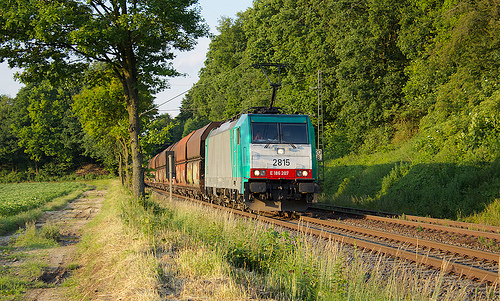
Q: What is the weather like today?
A: It is clear.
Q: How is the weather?
A: It is clear.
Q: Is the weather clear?
A: Yes, it is clear.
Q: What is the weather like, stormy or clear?
A: It is clear.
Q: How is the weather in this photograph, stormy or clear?
A: It is clear.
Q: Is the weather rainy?
A: No, it is clear.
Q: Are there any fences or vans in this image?
A: No, there are no fences or vans.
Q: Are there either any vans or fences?
A: No, there are no fences or vans.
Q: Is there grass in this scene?
A: Yes, there is grass.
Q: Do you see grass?
A: Yes, there is grass.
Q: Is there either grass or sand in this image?
A: Yes, there is grass.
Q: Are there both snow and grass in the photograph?
A: No, there is grass but no snow.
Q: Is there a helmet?
A: No, there are no helmets.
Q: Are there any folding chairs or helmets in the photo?
A: No, there are no helmets or folding chairs.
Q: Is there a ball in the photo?
A: No, there are no balls.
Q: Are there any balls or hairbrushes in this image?
A: No, there are no balls or hairbrushes.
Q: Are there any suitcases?
A: No, there are no suitcases.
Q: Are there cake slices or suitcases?
A: No, there are no suitcases or cake slices.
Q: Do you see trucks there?
A: No, there are no trucks.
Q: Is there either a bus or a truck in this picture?
A: No, there are no trucks or buses.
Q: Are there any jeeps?
A: No, there are no jeeps.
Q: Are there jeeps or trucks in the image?
A: No, there are no jeeps or trucks.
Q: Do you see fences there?
A: No, there are no fences.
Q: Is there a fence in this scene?
A: No, there are no fences.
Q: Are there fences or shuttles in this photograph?
A: No, there are no fences or shuttles.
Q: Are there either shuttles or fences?
A: No, there are no fences or shuttles.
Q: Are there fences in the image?
A: No, there are no fences.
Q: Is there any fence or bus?
A: No, there are no fences or buses.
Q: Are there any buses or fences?
A: No, there are no fences or buses.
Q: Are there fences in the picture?
A: No, there are no fences.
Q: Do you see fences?
A: No, there are no fences.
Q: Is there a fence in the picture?
A: No, there are no fences.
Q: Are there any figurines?
A: No, there are no figurines.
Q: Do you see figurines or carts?
A: No, there are no figurines or carts.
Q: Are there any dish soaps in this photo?
A: No, there are no dish soaps.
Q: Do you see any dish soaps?
A: No, there are no dish soaps.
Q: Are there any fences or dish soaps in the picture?
A: No, there are no dish soaps or fences.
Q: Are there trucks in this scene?
A: No, there are no trucks.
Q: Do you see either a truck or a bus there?
A: No, there are no trucks or buses.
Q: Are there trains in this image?
A: Yes, there is a train.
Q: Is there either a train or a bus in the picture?
A: Yes, there is a train.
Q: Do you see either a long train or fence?
A: Yes, there is a long train.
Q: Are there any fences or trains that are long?
A: Yes, the train is long.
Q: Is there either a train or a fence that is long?
A: Yes, the train is long.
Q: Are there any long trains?
A: Yes, there is a long train.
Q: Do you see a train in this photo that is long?
A: Yes, there is a train that is long.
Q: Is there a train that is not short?
A: Yes, there is a long train.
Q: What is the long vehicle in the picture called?
A: The vehicle is a train.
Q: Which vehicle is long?
A: The vehicle is a train.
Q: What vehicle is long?
A: The vehicle is a train.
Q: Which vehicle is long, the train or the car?
A: The train is long.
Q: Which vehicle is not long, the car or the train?
A: The car is not long.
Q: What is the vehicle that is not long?
A: The vehicle is a car.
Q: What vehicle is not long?
A: The vehicle is a car.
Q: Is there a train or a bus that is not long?
A: No, there is a train but it is long.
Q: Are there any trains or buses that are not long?
A: No, there is a train but it is long.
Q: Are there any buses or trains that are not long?
A: No, there is a train but it is long.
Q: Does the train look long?
A: Yes, the train is long.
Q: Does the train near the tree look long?
A: Yes, the train is long.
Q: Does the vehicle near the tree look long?
A: Yes, the train is long.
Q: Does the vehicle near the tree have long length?
A: Yes, the train is long.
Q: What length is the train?
A: The train is long.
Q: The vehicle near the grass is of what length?
A: The train is long.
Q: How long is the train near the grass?
A: The train is long.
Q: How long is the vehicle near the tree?
A: The train is long.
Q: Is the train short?
A: No, the train is long.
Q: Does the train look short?
A: No, the train is long.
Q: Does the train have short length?
A: No, the train is long.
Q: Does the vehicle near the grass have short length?
A: No, the train is long.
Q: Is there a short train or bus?
A: No, there is a train but it is long.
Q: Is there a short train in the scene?
A: No, there is a train but it is long.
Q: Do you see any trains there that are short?
A: No, there is a train but it is long.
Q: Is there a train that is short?
A: No, there is a train but it is long.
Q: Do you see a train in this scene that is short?
A: No, there is a train but it is long.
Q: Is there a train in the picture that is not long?
A: No, there is a train but it is long.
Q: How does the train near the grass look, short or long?
A: The train is long.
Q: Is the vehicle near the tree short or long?
A: The train is long.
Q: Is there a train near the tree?
A: Yes, there is a train near the tree.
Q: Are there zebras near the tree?
A: No, there is a train near the tree.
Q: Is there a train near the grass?
A: Yes, there is a train near the grass.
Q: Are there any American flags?
A: No, there are no American flags.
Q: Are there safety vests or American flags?
A: No, there are no American flags or safety vests.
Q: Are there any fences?
A: No, there are no fences.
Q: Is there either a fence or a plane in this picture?
A: No, there are no fences or airplanes.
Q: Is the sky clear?
A: Yes, the sky is clear.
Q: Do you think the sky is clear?
A: Yes, the sky is clear.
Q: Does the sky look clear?
A: Yes, the sky is clear.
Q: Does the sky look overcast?
A: No, the sky is clear.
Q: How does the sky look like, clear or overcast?
A: The sky is clear.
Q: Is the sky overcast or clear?
A: The sky is clear.